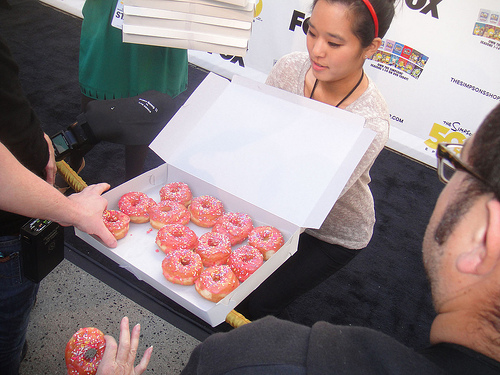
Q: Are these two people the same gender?
A: No, they are both male and female.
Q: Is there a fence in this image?
A: No, there are no fences.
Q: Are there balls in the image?
A: No, there are no balls.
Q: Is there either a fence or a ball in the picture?
A: No, there are no balls or fences.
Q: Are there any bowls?
A: No, there are no bowls.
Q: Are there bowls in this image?
A: No, there are no bowls.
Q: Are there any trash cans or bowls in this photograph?
A: No, there are no bowls or trash cans.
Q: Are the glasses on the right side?
A: Yes, the glasses are on the right of the image.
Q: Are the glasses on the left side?
A: No, the glasses are on the right of the image.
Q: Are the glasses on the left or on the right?
A: The glasses are on the right of the image.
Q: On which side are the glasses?
A: The glasses are on the right of the image.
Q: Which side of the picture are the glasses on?
A: The glasses are on the right of the image.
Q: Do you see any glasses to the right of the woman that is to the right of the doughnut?
A: Yes, there are glasses to the right of the woman.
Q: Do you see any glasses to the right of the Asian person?
A: Yes, there are glasses to the right of the woman.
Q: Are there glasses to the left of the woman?
A: No, the glasses are to the right of the woman.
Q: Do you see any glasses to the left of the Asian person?
A: No, the glasses are to the right of the woman.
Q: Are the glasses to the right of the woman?
A: Yes, the glasses are to the right of the woman.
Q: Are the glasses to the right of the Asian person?
A: Yes, the glasses are to the right of the woman.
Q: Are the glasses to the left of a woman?
A: No, the glasses are to the right of a woman.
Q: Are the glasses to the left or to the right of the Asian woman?
A: The glasses are to the right of the woman.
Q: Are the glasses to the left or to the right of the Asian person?
A: The glasses are to the right of the woman.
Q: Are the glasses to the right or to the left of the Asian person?
A: The glasses are to the right of the woman.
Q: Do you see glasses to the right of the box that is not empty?
A: Yes, there are glasses to the right of the box.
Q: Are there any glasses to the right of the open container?
A: Yes, there are glasses to the right of the box.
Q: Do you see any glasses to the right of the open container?
A: Yes, there are glasses to the right of the box.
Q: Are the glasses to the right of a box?
A: Yes, the glasses are to the right of a box.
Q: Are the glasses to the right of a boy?
A: No, the glasses are to the right of a box.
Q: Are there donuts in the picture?
A: Yes, there is a donut.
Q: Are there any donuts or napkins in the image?
A: Yes, there is a donut.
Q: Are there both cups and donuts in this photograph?
A: No, there is a donut but no cups.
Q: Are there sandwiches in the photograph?
A: No, there are no sandwiches.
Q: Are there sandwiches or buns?
A: No, there are no sandwiches or buns.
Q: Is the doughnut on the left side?
A: Yes, the doughnut is on the left of the image.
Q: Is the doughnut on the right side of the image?
A: No, the doughnut is on the left of the image.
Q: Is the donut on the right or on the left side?
A: The donut is on the left of the image.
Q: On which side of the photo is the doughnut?
A: The doughnut is on the left of the image.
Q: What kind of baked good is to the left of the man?
A: The food is a donut.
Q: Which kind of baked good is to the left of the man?
A: The food is a donut.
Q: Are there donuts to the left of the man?
A: Yes, there is a donut to the left of the man.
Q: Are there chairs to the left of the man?
A: No, there is a donut to the left of the man.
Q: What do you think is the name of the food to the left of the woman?
A: The food is a donut.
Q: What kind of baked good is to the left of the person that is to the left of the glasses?
A: The food is a donut.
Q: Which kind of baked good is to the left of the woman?
A: The food is a donut.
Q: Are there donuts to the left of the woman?
A: Yes, there is a donut to the left of the woman.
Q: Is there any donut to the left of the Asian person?
A: Yes, there is a donut to the left of the woman.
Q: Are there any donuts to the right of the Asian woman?
A: No, the donut is to the left of the woman.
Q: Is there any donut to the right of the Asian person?
A: No, the donut is to the left of the woman.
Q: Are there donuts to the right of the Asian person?
A: No, the donut is to the left of the woman.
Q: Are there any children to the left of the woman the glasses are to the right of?
A: No, there is a donut to the left of the woman.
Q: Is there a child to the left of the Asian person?
A: No, there is a donut to the left of the woman.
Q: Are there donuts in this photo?
A: Yes, there is a donut.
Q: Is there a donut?
A: Yes, there is a donut.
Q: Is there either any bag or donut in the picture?
A: Yes, there is a donut.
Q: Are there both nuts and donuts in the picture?
A: No, there is a donut but no nuts.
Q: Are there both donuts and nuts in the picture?
A: No, there is a donut but no nuts.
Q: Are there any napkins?
A: No, there are no napkins.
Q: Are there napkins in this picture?
A: No, there are no napkins.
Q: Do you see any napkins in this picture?
A: No, there are no napkins.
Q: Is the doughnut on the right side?
A: No, the doughnut is on the left of the image.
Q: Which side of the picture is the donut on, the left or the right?
A: The donut is on the left of the image.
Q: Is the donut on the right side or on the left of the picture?
A: The donut is on the left of the image.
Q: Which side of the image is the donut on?
A: The donut is on the left of the image.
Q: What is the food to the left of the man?
A: The food is a donut.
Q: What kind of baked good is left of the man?
A: The food is a donut.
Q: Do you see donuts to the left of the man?
A: Yes, there is a donut to the left of the man.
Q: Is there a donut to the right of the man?
A: No, the donut is to the left of the man.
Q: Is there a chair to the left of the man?
A: No, there is a donut to the left of the man.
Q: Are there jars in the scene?
A: No, there are no jars.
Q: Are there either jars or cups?
A: No, there are no jars or cups.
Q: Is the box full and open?
A: Yes, the box is full and open.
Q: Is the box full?
A: Yes, the box is full.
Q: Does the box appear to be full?
A: Yes, the box is full.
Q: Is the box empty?
A: No, the box is full.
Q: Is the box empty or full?
A: The box is full.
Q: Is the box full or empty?
A: The box is full.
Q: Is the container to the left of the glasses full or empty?
A: The box is full.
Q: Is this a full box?
A: Yes, this is a full box.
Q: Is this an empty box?
A: No, this is a full box.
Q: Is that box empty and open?
A: No, the box is open but full.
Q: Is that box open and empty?
A: No, the box is open but full.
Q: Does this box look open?
A: Yes, the box is open.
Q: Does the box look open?
A: Yes, the box is open.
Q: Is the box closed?
A: No, the box is open.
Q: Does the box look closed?
A: No, the box is open.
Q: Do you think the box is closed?
A: No, the box is open.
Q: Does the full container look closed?
A: No, the box is open.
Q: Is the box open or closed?
A: The box is open.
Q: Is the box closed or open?
A: The box is open.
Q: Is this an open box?
A: Yes, this is an open box.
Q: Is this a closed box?
A: No, this is an open box.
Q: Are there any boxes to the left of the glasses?
A: Yes, there is a box to the left of the glasses.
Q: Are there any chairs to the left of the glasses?
A: No, there is a box to the left of the glasses.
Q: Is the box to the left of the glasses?
A: Yes, the box is to the left of the glasses.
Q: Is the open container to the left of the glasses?
A: Yes, the box is to the left of the glasses.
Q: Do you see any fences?
A: No, there are no fences.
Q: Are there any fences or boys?
A: No, there are no fences or boys.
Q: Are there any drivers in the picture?
A: No, there are no drivers.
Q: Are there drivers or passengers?
A: No, there are no drivers or passengers.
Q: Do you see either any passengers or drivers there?
A: No, there are no drivers or passengers.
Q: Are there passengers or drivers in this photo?
A: No, there are no drivers or passengers.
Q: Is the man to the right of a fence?
A: No, the man is to the right of a donut.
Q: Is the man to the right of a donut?
A: Yes, the man is to the right of a donut.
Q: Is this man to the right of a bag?
A: No, the man is to the right of a donut.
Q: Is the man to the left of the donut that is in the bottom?
A: No, the man is to the right of the doughnut.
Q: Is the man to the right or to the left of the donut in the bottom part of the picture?
A: The man is to the right of the doughnut.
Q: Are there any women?
A: Yes, there is a woman.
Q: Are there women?
A: Yes, there is a woman.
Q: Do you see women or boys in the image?
A: Yes, there is a woman.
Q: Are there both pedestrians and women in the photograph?
A: No, there is a woman but no pedestrians.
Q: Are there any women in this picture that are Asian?
A: Yes, there is an Asian woman.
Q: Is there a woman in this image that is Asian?
A: Yes, there is a woman that is asian.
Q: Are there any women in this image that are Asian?
A: Yes, there is a woman that is asian.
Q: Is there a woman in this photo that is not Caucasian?
A: Yes, there is a Asian woman.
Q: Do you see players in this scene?
A: No, there are no players.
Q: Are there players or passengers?
A: No, there are no players or passengers.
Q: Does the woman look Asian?
A: Yes, the woman is asian.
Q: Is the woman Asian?
A: Yes, the woman is asian.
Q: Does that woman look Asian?
A: Yes, the woman is asian.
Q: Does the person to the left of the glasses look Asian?
A: Yes, the woman is asian.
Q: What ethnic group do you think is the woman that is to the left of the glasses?
A: The woman is asian.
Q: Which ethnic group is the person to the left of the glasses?
A: The woman is asian.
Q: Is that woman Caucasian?
A: No, the woman is asian.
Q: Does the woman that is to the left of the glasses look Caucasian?
A: No, the woman is asian.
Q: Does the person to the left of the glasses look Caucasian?
A: No, the woman is asian.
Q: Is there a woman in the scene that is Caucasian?
A: No, there is a woman but she is asian.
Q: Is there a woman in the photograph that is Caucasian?
A: No, there is a woman but she is asian.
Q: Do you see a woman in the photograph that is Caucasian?
A: No, there is a woman but she is asian.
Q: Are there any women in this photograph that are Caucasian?
A: No, there is a woman but she is asian.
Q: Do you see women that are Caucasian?
A: No, there is a woman but she is asian.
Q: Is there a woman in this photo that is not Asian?
A: No, there is a woman but she is asian.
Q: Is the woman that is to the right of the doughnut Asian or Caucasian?
A: The woman is asian.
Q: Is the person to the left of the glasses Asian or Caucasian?
A: The woman is asian.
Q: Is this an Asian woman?
A: Yes, this is an Asian woman.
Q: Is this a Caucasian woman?
A: No, this is an Asian woman.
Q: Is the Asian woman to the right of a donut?
A: Yes, the woman is to the right of a donut.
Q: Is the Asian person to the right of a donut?
A: Yes, the woman is to the right of a donut.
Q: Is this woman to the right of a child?
A: No, the woman is to the right of a donut.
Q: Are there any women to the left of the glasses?
A: Yes, there is a woman to the left of the glasses.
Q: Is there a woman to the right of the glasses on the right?
A: No, the woman is to the left of the glasses.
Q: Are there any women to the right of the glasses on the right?
A: No, the woman is to the left of the glasses.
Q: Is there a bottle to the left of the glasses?
A: No, there is a woman to the left of the glasses.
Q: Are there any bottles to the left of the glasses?
A: No, there is a woman to the left of the glasses.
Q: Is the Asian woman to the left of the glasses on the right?
A: Yes, the woman is to the left of the glasses.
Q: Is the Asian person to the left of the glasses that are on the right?
A: Yes, the woman is to the left of the glasses.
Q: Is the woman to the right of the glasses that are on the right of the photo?
A: No, the woman is to the left of the glasses.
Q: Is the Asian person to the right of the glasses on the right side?
A: No, the woman is to the left of the glasses.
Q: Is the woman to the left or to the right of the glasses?
A: The woman is to the left of the glasses.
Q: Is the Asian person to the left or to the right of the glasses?
A: The woman is to the left of the glasses.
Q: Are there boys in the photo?
A: No, there are no boys.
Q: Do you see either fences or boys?
A: No, there are no boys or fences.